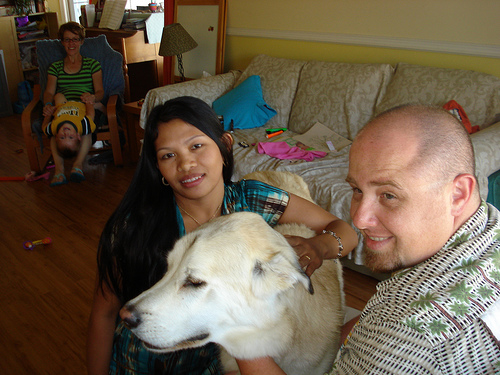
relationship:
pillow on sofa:
[213, 75, 276, 134] [141, 48, 496, 212]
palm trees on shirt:
[404, 250, 498, 333] [313, 194, 496, 371]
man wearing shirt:
[237, 102, 499, 373] [313, 194, 496, 371]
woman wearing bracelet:
[85, 95, 359, 374] [318, 221, 348, 256]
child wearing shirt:
[37, 89, 102, 149] [39, 88, 104, 142]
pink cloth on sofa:
[252, 138, 329, 162] [137, 54, 497, 275]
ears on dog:
[250, 255, 315, 296] [121, 170, 346, 373]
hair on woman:
[116, 88, 247, 274] [85, 95, 357, 374]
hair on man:
[360, 97, 484, 206] [237, 102, 499, 373]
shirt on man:
[313, 194, 496, 371] [329, 129, 494, 371]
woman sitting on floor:
[85, 95, 359, 374] [4, 103, 141, 373]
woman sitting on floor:
[43, 20, 105, 188] [4, 103, 141, 373]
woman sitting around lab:
[85, 95, 359, 374] [118, 171, 346, 373]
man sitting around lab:
[237, 102, 499, 373] [118, 171, 346, 373]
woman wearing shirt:
[85, 95, 357, 374] [39, 55, 103, 105]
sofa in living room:
[137, 54, 499, 282] [9, 4, 489, 373]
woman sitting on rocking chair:
[48, 17, 107, 182] [23, 28, 129, 203]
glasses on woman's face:
[58, 34, 81, 45] [53, 17, 91, 59]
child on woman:
[37, 89, 102, 149] [38, 12, 106, 188]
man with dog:
[237, 102, 499, 373] [121, 170, 346, 373]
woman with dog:
[85, 95, 357, 374] [121, 170, 346, 373]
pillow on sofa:
[213, 75, 276, 134] [137, 54, 497, 275]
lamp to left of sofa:
[146, 17, 201, 83] [246, 36, 359, 142]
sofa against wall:
[137, 54, 497, 275] [226, 0, 498, 82]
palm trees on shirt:
[409, 239, 498, 335] [327, 198, 497, 373]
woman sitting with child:
[43, 20, 105, 188] [37, 89, 102, 149]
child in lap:
[37, 89, 102, 149] [28, 82, 105, 136]